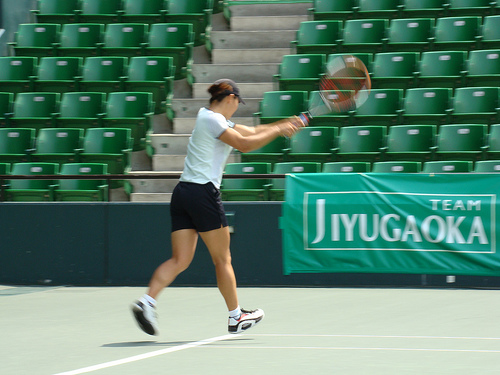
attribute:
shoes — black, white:
[127, 290, 269, 342]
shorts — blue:
[164, 178, 238, 237]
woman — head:
[131, 76, 308, 336]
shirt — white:
[178, 106, 233, 191]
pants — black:
[169, 180, 229, 231]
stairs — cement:
[122, 3, 309, 207]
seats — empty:
[416, 50, 466, 82]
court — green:
[15, 181, 490, 369]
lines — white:
[93, 286, 227, 373]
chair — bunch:
[389, 123, 438, 158]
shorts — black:
[166, 178, 229, 233]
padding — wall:
[50, 204, 145, 285]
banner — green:
[294, 176, 491, 273]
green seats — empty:
[220, 2, 498, 199]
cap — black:
[208, 78, 248, 102]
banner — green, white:
[278, 170, 499, 279]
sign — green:
[280, 164, 498, 286]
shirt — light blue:
[181, 105, 231, 187]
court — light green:
[0, 283, 498, 373]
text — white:
[295, 162, 480, 282]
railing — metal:
[7, 170, 287, 178]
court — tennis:
[304, 285, 488, 373]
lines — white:
[61, 331, 240, 373]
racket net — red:
[319, 60, 371, 113]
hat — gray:
[192, 69, 277, 124]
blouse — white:
[175, 100, 239, 194]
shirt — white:
[178, 101, 235, 188]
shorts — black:
[164, 177, 233, 234]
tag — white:
[99, 60, 127, 68]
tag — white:
[436, 51, 452, 64]